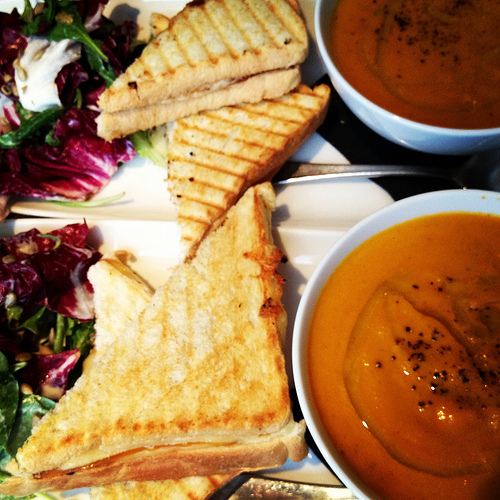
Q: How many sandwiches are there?
A: Four sandwiches.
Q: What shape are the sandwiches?
A: They are shaped like triangles.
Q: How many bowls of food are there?
A: Two bowls of food.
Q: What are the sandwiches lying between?
A: The sandwiches are between bowls and lettuce.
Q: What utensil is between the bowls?
A: A spoon.